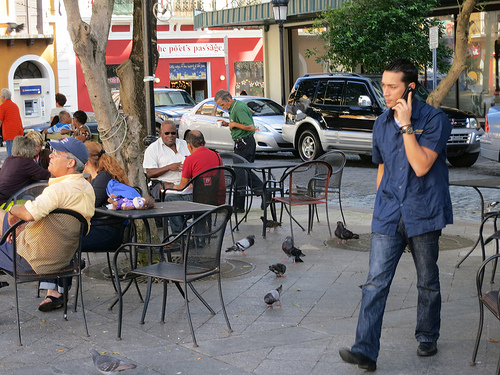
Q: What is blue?
A: Man's shirt.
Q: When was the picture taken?
A: Daytime.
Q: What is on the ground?
A: Birds.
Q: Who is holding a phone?
A: Man in blue.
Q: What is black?
A: Tables.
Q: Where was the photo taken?
A: At a cafe.